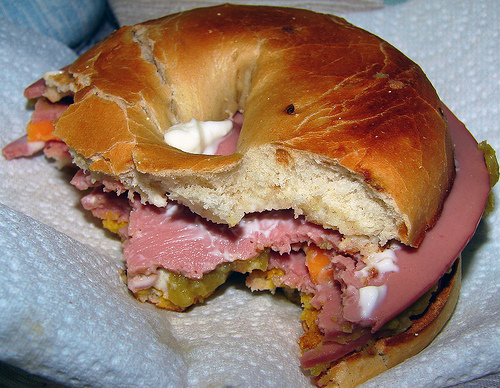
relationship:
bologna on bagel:
[3, 63, 492, 370] [3, 0, 499, 388]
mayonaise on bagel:
[165, 116, 235, 157] [3, 0, 499, 388]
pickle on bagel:
[163, 249, 274, 308] [3, 0, 499, 388]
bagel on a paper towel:
[3, 0, 499, 388] [1, 2, 500, 387]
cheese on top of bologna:
[25, 121, 63, 147] [3, 63, 492, 370]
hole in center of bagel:
[153, 86, 262, 163] [3, 0, 499, 388]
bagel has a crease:
[3, 0, 499, 388] [128, 23, 182, 123]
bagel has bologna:
[3, 0, 499, 388] [3, 63, 492, 370]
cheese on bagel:
[25, 121, 63, 147] [3, 0, 499, 388]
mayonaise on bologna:
[165, 116, 235, 157] [3, 63, 492, 370]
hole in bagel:
[153, 86, 262, 163] [3, 0, 499, 388]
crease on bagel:
[128, 23, 182, 123] [3, 0, 499, 388]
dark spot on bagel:
[329, 56, 432, 153] [3, 0, 499, 388]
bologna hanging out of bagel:
[3, 63, 492, 370] [3, 0, 499, 388]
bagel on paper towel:
[3, 0, 499, 388] [1, 2, 500, 387]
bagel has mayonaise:
[3, 0, 499, 388] [165, 116, 235, 157]